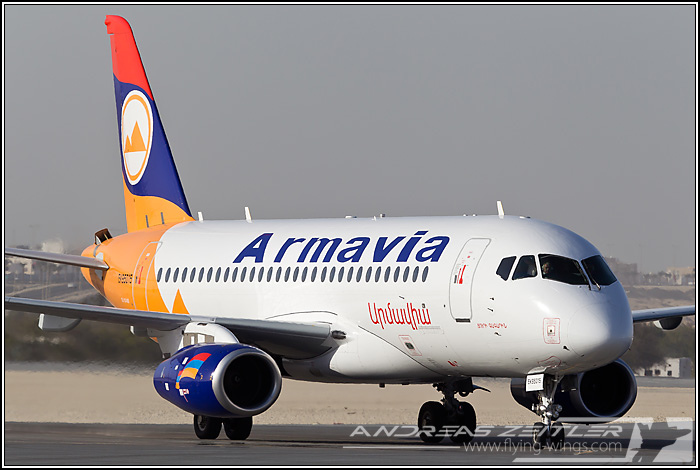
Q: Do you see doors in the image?
A: Yes, there is a door.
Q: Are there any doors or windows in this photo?
A: Yes, there is a door.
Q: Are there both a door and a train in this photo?
A: No, there is a door but no trains.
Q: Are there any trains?
A: No, there are no trains.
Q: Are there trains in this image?
A: No, there are no trains.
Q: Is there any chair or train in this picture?
A: No, there are no trains or chairs.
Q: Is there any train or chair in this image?
A: No, there are no trains or chairs.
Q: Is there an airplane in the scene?
A: Yes, there is an airplane.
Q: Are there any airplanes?
A: Yes, there is an airplane.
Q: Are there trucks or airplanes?
A: Yes, there is an airplane.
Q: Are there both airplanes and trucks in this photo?
A: No, there is an airplane but no trucks.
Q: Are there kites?
A: No, there are no kites.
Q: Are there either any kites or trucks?
A: No, there are no kites or trucks.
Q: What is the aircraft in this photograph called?
A: The aircraft is an airplane.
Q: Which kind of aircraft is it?
A: The aircraft is an airplane.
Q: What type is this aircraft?
A: This is an airplane.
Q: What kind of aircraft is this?
A: This is an airplane.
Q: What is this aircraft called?
A: This is an airplane.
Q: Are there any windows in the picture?
A: Yes, there are windows.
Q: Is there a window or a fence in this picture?
A: Yes, there are windows.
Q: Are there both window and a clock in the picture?
A: No, there are windows but no clocks.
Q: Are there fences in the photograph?
A: No, there are no fences.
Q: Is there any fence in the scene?
A: No, there are no fences.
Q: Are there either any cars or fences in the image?
A: No, there are no fences or cars.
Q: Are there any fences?
A: No, there are no fences.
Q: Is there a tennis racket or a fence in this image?
A: No, there are no fences or rackets.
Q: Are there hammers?
A: No, there are no hammers.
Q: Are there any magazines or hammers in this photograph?
A: No, there are no hammers or magazines.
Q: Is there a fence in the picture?
A: No, there are no fences.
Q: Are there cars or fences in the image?
A: No, there are no fences or cars.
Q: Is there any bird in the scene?
A: No, there are no birds.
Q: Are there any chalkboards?
A: No, there are no chalkboards.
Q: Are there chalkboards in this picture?
A: No, there are no chalkboards.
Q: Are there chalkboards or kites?
A: No, there are no chalkboards or kites.